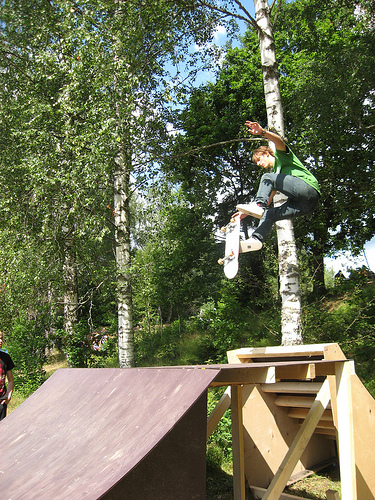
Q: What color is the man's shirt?
A: Green.